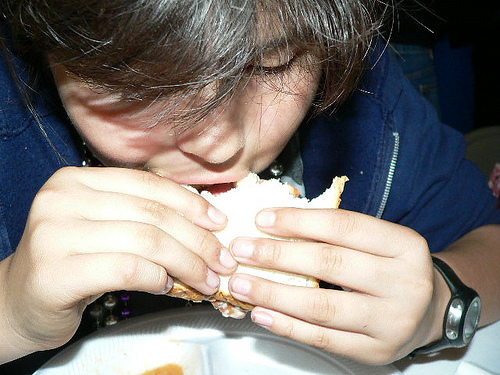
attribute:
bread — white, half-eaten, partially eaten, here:
[177, 167, 341, 308]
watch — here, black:
[424, 238, 478, 356]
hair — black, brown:
[3, 2, 399, 115]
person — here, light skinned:
[3, 4, 499, 368]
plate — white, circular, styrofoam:
[33, 303, 397, 373]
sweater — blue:
[2, 32, 494, 322]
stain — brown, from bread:
[137, 353, 177, 375]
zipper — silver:
[356, 128, 412, 220]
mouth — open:
[173, 164, 244, 199]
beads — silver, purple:
[77, 149, 305, 325]